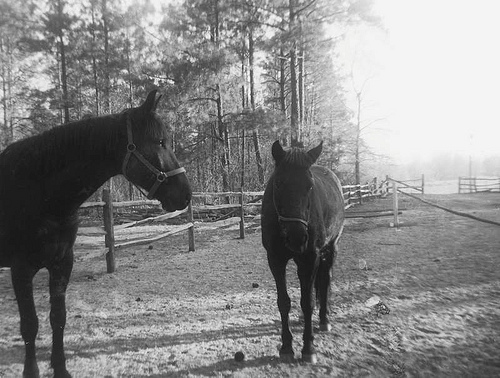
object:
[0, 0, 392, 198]
trees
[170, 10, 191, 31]
leaves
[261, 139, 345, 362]
horse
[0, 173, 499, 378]
pen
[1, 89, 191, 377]
horse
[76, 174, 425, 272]
fence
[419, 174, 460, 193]
gate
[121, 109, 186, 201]
bridle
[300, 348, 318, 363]
hoof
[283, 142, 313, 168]
forelock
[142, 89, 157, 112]
black ear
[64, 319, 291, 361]
shadow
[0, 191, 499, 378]
dirt ground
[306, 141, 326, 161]
black ears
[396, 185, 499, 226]
log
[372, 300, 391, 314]
dirt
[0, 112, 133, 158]
mane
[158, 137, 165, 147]
dark eyes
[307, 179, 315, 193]
dark eyes